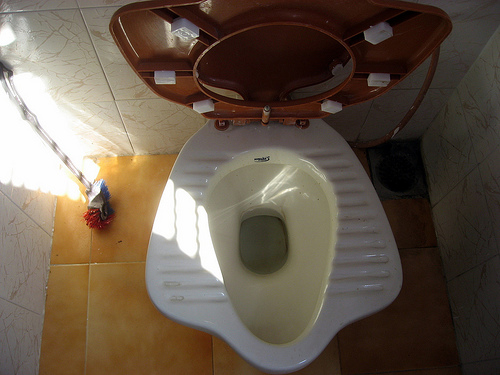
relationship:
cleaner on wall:
[373, 131, 430, 201] [452, 30, 484, 64]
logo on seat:
[249, 153, 271, 169] [125, 126, 420, 373]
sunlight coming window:
[19, 96, 77, 194] [1, 23, 61, 193]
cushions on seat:
[136, 34, 436, 140] [114, 10, 411, 175]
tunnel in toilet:
[237, 210, 292, 270] [109, 1, 456, 370]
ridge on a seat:
[187, 154, 236, 164] [148, 121, 408, 368]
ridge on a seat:
[303, 143, 345, 161] [148, 121, 408, 368]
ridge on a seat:
[155, 262, 210, 276] [148, 121, 408, 368]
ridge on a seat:
[338, 241, 391, 251] [148, 121, 408, 368]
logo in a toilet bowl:
[253, 156, 271, 163] [106, 0, 451, 368]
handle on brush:
[4, 75, 90, 192] [83, 177, 117, 231]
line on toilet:
[173, 180, 209, 192] [109, 1, 456, 370]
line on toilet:
[153, 250, 208, 257] [109, 1, 456, 370]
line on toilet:
[157, 291, 229, 303] [109, 1, 456, 370]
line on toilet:
[339, 240, 388, 250] [109, 1, 456, 370]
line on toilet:
[335, 199, 369, 210] [109, 1, 456, 370]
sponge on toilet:
[169, 17, 201, 47] [109, 1, 456, 370]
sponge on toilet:
[365, 70, 392, 89] [109, 1, 456, 370]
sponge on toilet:
[187, 99, 217, 115] [109, 1, 456, 370]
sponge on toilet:
[363, 21, 393, 44] [109, 1, 456, 370]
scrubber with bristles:
[2, 72, 116, 223] [86, 209, 107, 228]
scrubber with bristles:
[2, 72, 116, 223] [95, 180, 114, 213]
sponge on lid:
[363, 21, 393, 45] [141, 6, 428, 166]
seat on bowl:
[141, 109, 404, 371] [237, 177, 322, 299]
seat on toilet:
[141, 109, 404, 371] [122, 33, 398, 373]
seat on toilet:
[141, 109, 404, 371] [161, 126, 399, 349]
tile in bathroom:
[57, 277, 117, 339] [45, 163, 200, 301]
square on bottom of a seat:
[147, 67, 177, 87] [103, 6, 453, 132]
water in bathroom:
[212, 180, 337, 342] [45, 117, 496, 375]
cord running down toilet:
[391, 42, 441, 141] [109, 1, 456, 370]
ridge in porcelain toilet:
[336, 250, 397, 267] [140, 117, 405, 373]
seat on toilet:
[137, 109, 403, 371] [143, 0, 455, 361]